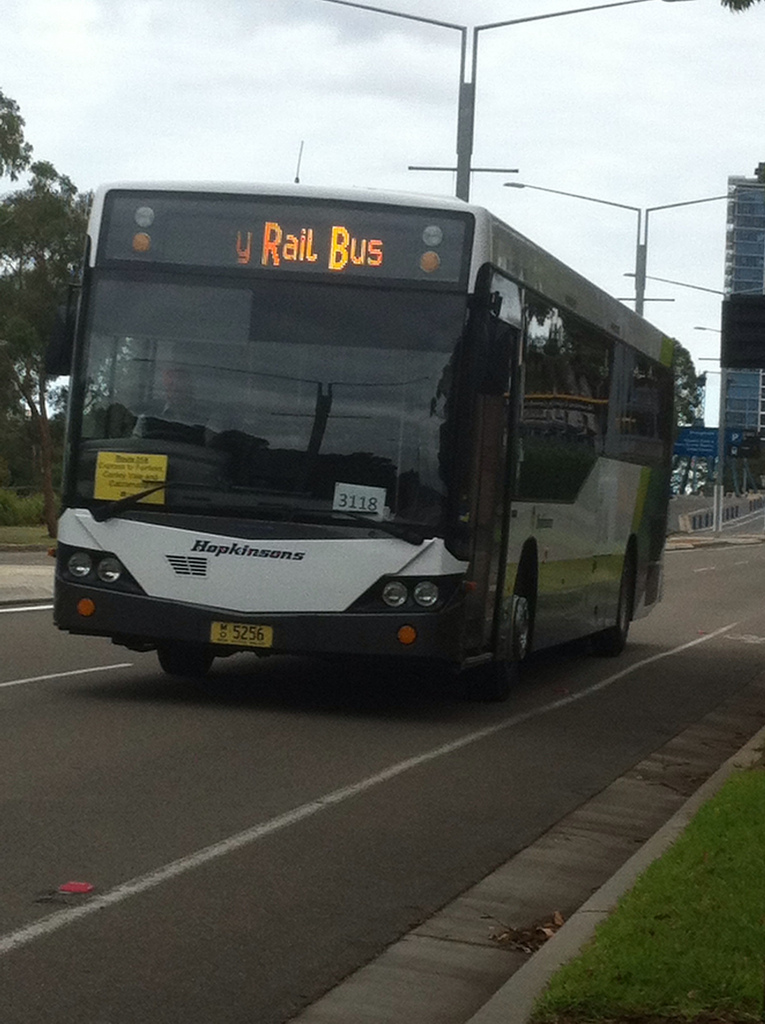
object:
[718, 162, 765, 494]
building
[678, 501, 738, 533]
rail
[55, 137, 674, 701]
bus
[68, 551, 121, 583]
headlights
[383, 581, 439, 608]
headlights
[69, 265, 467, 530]
windshield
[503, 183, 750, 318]
light post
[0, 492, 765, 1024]
street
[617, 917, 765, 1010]
patch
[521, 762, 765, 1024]
grass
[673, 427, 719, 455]
sign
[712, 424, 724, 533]
post